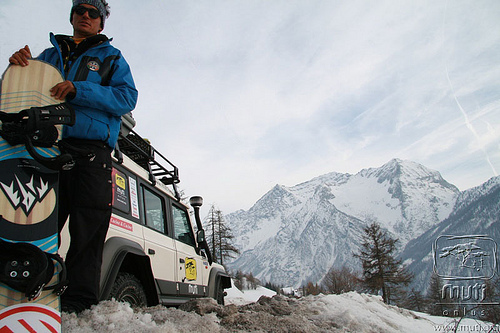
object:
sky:
[0, 0, 499, 214]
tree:
[358, 227, 413, 314]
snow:
[375, 289, 414, 319]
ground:
[323, 150, 355, 192]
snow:
[66, 274, 495, 331]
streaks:
[451, 97, 489, 154]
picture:
[183, 257, 197, 281]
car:
[101, 110, 236, 310]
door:
[166, 197, 204, 297]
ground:
[384, 92, 416, 129]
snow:
[227, 172, 492, 302]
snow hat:
[71, 2, 113, 22]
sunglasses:
[72, 6, 102, 19]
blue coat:
[32, 32, 138, 148]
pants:
[47, 134, 113, 313]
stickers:
[113, 168, 150, 219]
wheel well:
[107, 272, 149, 310]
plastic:
[100, 237, 150, 289]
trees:
[198, 200, 242, 283]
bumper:
[207, 267, 232, 288]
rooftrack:
[119, 120, 179, 186]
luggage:
[118, 133, 155, 162]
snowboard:
[0, 60, 71, 332]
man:
[9, 0, 141, 312]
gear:
[32, 130, 40, 141]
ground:
[6, 283, 486, 329]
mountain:
[207, 159, 499, 324]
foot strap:
[0, 239, 57, 298]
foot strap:
[3, 108, 63, 153]